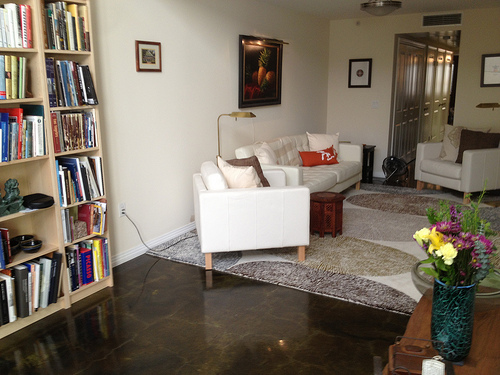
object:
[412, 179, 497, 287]
flowers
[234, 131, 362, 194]
sofa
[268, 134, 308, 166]
blanket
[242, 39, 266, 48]
light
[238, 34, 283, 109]
art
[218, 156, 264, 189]
pillow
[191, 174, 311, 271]
chair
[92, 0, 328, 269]
wall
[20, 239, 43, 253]
bowls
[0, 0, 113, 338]
book shelf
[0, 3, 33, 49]
books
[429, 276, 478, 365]
vase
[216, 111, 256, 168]
floor lamp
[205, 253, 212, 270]
leg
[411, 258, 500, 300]
bowl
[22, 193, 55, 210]
cd case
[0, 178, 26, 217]
chinese artwork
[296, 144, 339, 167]
pillow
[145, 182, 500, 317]
area rug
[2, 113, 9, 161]
blue book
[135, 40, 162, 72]
picture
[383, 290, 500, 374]
table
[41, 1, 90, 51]
books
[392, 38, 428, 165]
door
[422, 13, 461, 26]
air vent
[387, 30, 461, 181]
doorway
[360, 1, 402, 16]
ceiling light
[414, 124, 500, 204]
chair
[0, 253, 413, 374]
floor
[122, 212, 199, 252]
electrical wire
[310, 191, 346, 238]
end table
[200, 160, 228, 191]
cushion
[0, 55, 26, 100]
books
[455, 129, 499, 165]
pillow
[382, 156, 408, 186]
fan